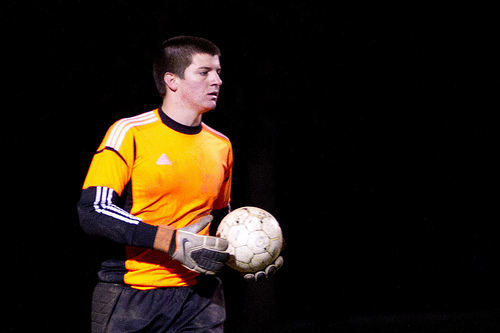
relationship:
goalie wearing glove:
[74, 31, 285, 331] [166, 212, 234, 277]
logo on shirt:
[154, 150, 174, 166] [78, 110, 231, 285]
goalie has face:
[74, 31, 285, 331] [178, 53, 222, 111]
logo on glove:
[181, 236, 189, 259] [166, 212, 234, 277]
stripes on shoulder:
[107, 109, 155, 149] [101, 108, 160, 162]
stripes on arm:
[94, 184, 141, 225] [76, 122, 174, 255]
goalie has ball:
[74, 31, 285, 331] [215, 206, 284, 270]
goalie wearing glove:
[74, 31, 285, 331] [240, 256, 284, 279]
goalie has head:
[74, 31, 285, 331] [150, 32, 222, 114]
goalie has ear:
[74, 31, 285, 331] [162, 69, 178, 92]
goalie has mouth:
[74, 31, 285, 331] [207, 89, 222, 98]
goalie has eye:
[74, 31, 285, 331] [197, 69, 211, 76]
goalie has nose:
[74, 31, 285, 331] [209, 70, 223, 86]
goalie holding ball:
[74, 31, 285, 331] [215, 206, 284, 270]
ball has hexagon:
[215, 206, 284, 270] [227, 223, 250, 248]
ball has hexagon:
[215, 206, 284, 270] [261, 213, 280, 239]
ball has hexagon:
[215, 206, 284, 270] [234, 244, 253, 263]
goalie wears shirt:
[74, 31, 285, 331] [78, 110, 231, 285]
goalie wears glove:
[74, 31, 285, 331] [166, 212, 234, 277]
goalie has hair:
[74, 31, 285, 331] [152, 32, 220, 96]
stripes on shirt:
[107, 109, 155, 149] [78, 110, 231, 285]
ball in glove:
[215, 206, 284, 270] [240, 256, 284, 279]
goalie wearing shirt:
[74, 31, 285, 331] [78, 110, 231, 285]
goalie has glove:
[74, 31, 285, 331] [166, 212, 234, 277]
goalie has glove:
[74, 31, 285, 331] [240, 256, 284, 279]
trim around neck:
[156, 105, 207, 134] [159, 90, 205, 124]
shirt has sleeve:
[78, 110, 231, 285] [77, 121, 158, 251]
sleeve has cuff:
[77, 121, 158, 251] [135, 217, 160, 249]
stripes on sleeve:
[94, 184, 141, 225] [77, 121, 158, 251]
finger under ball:
[242, 271, 254, 281] [215, 206, 284, 270]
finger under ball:
[255, 269, 266, 281] [215, 206, 284, 270]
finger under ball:
[266, 262, 277, 278] [215, 206, 284, 270]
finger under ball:
[274, 255, 285, 270] [215, 206, 284, 270]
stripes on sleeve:
[94, 184, 141, 225] [78, 186, 158, 247]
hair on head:
[152, 32, 220, 96] [150, 32, 222, 114]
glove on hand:
[166, 212, 234, 277] [156, 215, 262, 280]